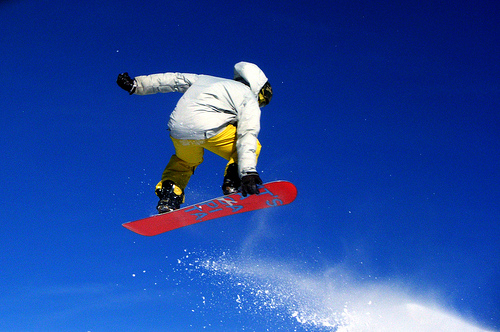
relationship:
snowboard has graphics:
[118, 178, 296, 238] [185, 179, 281, 217]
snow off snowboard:
[175, 242, 478, 330] [118, 178, 296, 238]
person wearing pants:
[116, 57, 272, 199] [157, 126, 264, 191]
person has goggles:
[116, 57, 272, 199] [263, 83, 271, 102]